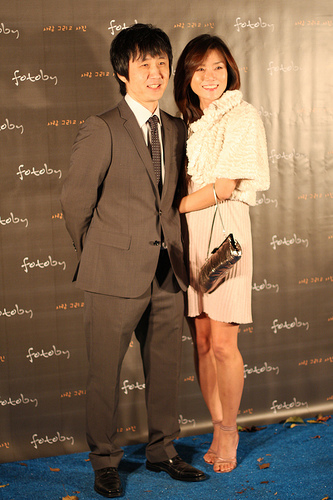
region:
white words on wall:
[12, 69, 76, 99]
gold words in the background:
[44, 292, 78, 319]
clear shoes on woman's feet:
[208, 446, 247, 484]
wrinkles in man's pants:
[134, 430, 182, 454]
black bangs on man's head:
[119, 39, 179, 65]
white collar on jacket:
[200, 95, 287, 141]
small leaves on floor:
[255, 443, 304, 484]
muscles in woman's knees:
[208, 344, 242, 393]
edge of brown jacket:
[63, 268, 134, 307]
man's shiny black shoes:
[91, 462, 211, 495]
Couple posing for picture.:
[53, 14, 289, 498]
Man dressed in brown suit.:
[54, 97, 185, 462]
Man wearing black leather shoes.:
[88, 459, 207, 498]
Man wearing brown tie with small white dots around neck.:
[147, 112, 167, 200]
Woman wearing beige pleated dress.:
[180, 85, 269, 326]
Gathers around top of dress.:
[186, 87, 252, 134]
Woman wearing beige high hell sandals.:
[200, 417, 248, 473]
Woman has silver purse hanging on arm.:
[197, 181, 251, 312]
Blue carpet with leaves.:
[243, 413, 328, 497]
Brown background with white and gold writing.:
[277, 145, 332, 397]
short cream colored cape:
[167, 104, 260, 206]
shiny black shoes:
[92, 452, 208, 499]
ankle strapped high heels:
[198, 405, 254, 481]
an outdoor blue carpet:
[254, 431, 324, 498]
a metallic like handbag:
[187, 180, 251, 296]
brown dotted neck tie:
[142, 114, 167, 191]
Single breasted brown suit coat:
[44, 108, 192, 296]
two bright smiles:
[132, 57, 227, 106]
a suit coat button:
[145, 227, 163, 251]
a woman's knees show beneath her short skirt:
[190, 319, 264, 368]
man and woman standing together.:
[40, 14, 290, 412]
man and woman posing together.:
[59, 13, 295, 421]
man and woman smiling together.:
[58, 21, 283, 365]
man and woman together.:
[65, 14, 283, 373]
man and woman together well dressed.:
[59, 13, 275, 359]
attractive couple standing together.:
[51, 10, 277, 368]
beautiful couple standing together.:
[63, 15, 278, 488]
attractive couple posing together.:
[58, 5, 276, 458]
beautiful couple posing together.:
[35, 12, 276, 475]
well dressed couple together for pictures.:
[58, 4, 292, 490]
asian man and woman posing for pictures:
[59, 18, 282, 287]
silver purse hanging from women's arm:
[192, 189, 243, 302]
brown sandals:
[202, 410, 245, 478]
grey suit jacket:
[59, 95, 196, 308]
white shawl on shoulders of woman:
[186, 91, 273, 213]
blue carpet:
[269, 430, 317, 490]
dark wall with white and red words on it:
[9, 49, 80, 135]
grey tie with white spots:
[141, 112, 173, 212]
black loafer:
[144, 445, 209, 488]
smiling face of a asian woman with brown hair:
[172, 28, 244, 109]